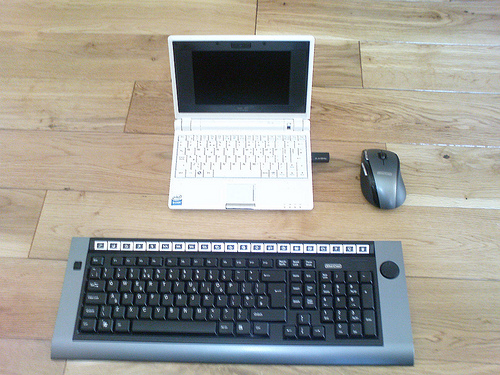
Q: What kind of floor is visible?
A: Wood.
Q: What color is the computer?
A: White.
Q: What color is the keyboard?
A: Black.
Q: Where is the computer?
A: Floor.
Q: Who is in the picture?
A: No one.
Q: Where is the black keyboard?
A: In front of the laptop.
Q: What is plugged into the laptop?
A: USB stick.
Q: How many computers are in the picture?
A: One.